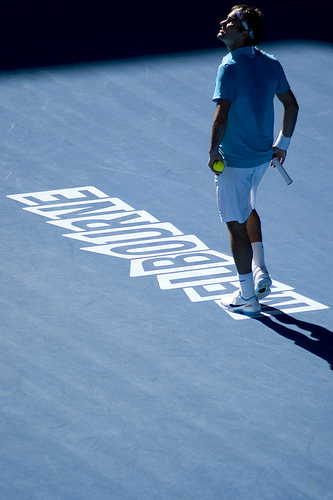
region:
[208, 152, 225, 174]
Yellow tennis ball in man's hand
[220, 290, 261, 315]
White Nike tennis shoe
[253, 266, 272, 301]
White tennis shoe lifted up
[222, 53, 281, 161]
Man wearing sweaty blue shirt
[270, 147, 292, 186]
Tennis racket in man's hand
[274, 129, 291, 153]
White sweatband on man's wrist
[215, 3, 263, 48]
White sweatband on man's head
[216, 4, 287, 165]
Man in blue shirt looking up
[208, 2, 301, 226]
Male tennis player in blue shirt and white shorts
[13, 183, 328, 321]
Blue and white letters on blue floor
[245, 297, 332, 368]
Black shadow of a man.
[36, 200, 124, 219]
The blue letter N on the floor.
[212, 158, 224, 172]
A bright green tennis ball.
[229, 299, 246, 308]
Black Nike swoosh on a white tennis shoe.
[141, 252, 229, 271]
A large blue letter B on the floor.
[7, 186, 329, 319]
The white blocks with blue letters that spell MELBOURNE on the floor.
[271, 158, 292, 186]
White handle of a tennis racket.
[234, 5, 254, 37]
White headband on a tennis player.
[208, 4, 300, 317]
A tennis player in a blue shirt and white shorts.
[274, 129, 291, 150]
A white wrap on a man's wrist.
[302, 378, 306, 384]
part of a court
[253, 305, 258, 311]
part of a shoe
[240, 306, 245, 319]
edge of a shoe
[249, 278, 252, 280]
part of a sock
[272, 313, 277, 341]
part of a shadow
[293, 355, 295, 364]
edge of a shadow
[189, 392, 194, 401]
edge of a court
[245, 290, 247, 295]
part of a sock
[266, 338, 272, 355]
edge of a shoe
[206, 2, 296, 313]
Man holding a ball and a tennis racquet.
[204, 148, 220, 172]
A green ball in left hand.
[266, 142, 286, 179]
Handle of a tennis racquet in the right hand.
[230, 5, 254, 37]
The player is wearing a white headband.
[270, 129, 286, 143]
A white wristband on the man's wrist.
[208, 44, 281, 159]
The tennis player wearing a blue shirt.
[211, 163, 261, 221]
The tennis player wearing white shorts.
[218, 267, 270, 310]
The tennis player wearing white tennis shoes.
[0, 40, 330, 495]
A blue tennis court.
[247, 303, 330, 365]
Shadow of the player on the tennis court.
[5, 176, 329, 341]
white framed blue letters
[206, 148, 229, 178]
tennis ball held in left hand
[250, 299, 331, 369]
the shadow of a man's legs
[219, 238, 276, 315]
white sneakers and crew socks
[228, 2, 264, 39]
sweatband on a mans head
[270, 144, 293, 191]
white grip of a tennis racquet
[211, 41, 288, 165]
blue shirt with perspiration on back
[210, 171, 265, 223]
loose fit white shorts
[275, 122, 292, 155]
a white wrist band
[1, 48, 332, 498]
blue tarp on the tennis court